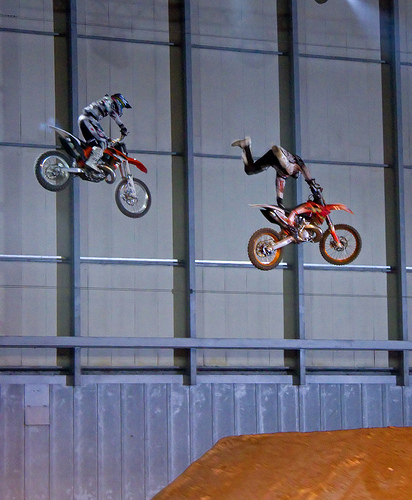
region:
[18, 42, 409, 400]
people riding dirt bikes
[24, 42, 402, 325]
two people on dirt bikes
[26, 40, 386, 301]
people doing tricks on dirt bike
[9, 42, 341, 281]
people doing stunts on dirt bikes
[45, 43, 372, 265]
dirt bikes in the air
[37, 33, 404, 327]
dirt bikes flying in the air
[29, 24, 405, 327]
two people in the air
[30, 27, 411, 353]
two dirt bikers in the air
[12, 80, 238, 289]
a person standing up on dirt bike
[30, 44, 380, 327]
two dirt bikers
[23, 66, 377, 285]
two motorcycles in the air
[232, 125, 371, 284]
motorcycle with rider standing on hands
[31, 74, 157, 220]
motorcycle rider with white boots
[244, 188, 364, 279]
red motorcycle with high fenders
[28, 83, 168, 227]
red and black motorcycle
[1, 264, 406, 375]
horizontal row of four windows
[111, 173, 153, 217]
front wheel of a motorcycle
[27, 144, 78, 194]
back wheel of a motorcycle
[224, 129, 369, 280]
motorcycle rider doing a trick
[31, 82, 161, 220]
motorcycle rider with a helment on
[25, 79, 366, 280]
these two people are on dirt bikes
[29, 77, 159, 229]
this person and dirt bike are not touching the ground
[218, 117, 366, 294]
this dirt bike is also in the air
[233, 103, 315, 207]
this person is perfoming trick on their dirt bike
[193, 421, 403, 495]
this portion of the track slopes upward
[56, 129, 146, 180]
this dirt bike is red and black in color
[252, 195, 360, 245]
this dirt bike is red and orange in color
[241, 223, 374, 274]
the dirt bikes wheels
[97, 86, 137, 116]
the person is wearing a helmet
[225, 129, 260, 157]
this rider is wearing white shoes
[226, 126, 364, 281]
The person is doing motorcycle tricks in air.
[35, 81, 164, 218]
The person is on a motorcycle.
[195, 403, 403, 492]
The ramp is brown.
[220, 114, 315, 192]
The person legs are in the air.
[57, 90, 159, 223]
The person is standing on the motorcycle.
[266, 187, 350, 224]
The motorcycle is red.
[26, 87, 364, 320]
Two motorcycles in the air.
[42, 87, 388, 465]
Two motorcycles jumping over a ramp.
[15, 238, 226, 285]
The building has iron rods across the wall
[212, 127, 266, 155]
The person shoes is white.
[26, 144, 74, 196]
The back wheel of the second bike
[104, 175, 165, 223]
The front wheel of the second bike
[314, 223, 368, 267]
The front wheel of the first bike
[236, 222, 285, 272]
The back wheel of the second bike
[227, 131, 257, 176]
The left leg of the first rider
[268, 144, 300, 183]
The right leg of the first rider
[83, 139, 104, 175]
The right leg of the second rider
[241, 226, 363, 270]
The bottom portion of a motorcycle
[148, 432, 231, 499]
The back portion of a sand mound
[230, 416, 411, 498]
The front portion of a sand mound